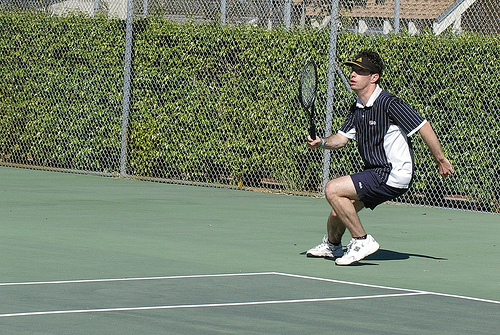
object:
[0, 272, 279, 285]
line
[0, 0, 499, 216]
fence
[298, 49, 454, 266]
he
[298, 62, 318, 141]
racket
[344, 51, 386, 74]
hat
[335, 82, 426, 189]
shirt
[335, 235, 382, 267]
shoes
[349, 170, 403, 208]
shorts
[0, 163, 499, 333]
court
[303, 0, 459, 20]
roof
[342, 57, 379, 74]
visor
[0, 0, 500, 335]
tennis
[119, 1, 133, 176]
pole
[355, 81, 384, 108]
collar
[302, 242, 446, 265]
shadow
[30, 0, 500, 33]
neighborhood